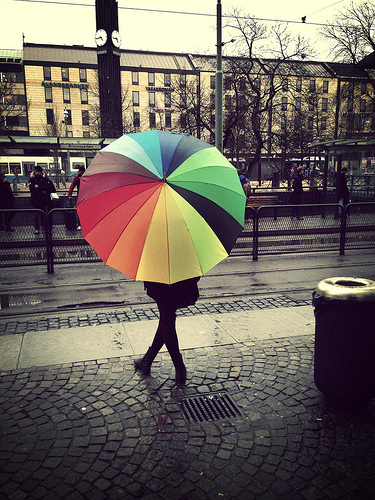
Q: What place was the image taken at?
A: It was taken at the sidewalk.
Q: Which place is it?
A: It is a sidewalk.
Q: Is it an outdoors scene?
A: Yes, it is outdoors.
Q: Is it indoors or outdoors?
A: It is outdoors.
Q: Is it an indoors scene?
A: No, it is outdoors.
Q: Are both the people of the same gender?
A: No, they are both male and female.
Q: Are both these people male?
A: No, they are both male and female.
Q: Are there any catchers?
A: No, there are no catchers.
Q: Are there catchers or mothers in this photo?
A: No, there are no catchers or mothers.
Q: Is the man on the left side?
A: Yes, the man is on the left of the image.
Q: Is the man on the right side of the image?
A: No, the man is on the left of the image.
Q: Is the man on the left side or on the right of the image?
A: The man is on the left of the image.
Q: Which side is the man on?
A: The man is on the left of the image.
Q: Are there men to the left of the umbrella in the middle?
A: Yes, there is a man to the left of the umbrella.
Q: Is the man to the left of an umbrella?
A: Yes, the man is to the left of an umbrella.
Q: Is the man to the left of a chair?
A: No, the man is to the left of an umbrella.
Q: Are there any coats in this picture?
A: Yes, there is a coat.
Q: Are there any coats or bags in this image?
A: Yes, there is a coat.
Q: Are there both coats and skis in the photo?
A: No, there is a coat but no skis.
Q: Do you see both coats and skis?
A: No, there is a coat but no skis.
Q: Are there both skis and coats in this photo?
A: No, there is a coat but no skis.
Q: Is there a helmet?
A: No, there are no helmets.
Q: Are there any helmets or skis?
A: No, there are no helmets or skis.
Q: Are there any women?
A: Yes, there is a woman.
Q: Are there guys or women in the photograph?
A: Yes, there is a woman.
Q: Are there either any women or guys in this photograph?
A: Yes, there is a woman.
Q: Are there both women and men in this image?
A: Yes, there are both a woman and a man.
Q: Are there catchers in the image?
A: No, there are no catchers.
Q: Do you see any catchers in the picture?
A: No, there are no catchers.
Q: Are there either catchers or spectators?
A: No, there are no catchers or spectators.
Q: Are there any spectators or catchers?
A: No, there are no catchers or spectators.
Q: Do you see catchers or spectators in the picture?
A: No, there are no catchers or spectators.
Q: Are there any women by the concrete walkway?
A: Yes, there is a woman by the walkway.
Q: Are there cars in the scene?
A: No, there are no cars.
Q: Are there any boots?
A: Yes, there are boots.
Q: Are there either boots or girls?
A: Yes, there are boots.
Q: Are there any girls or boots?
A: Yes, there are boots.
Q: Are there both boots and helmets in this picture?
A: No, there are boots but no helmets.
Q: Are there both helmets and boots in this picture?
A: No, there are boots but no helmets.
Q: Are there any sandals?
A: No, there are no sandals.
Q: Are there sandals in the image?
A: No, there are no sandals.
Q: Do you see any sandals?
A: No, there are no sandals.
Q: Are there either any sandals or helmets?
A: No, there are no sandals or helmets.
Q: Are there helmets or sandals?
A: No, there are no sandals or helmets.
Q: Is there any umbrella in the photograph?
A: Yes, there is an umbrella.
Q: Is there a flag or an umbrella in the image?
A: Yes, there is an umbrella.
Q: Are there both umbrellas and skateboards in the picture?
A: No, there is an umbrella but no skateboards.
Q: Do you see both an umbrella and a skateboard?
A: No, there is an umbrella but no skateboards.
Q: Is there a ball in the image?
A: No, there are no balls.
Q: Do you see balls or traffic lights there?
A: No, there are no balls or traffic lights.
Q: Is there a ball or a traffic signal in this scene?
A: No, there are no balls or traffic lights.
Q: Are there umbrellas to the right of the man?
A: Yes, there is an umbrella to the right of the man.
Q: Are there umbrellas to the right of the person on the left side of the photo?
A: Yes, there is an umbrella to the right of the man.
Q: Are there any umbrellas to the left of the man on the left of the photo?
A: No, the umbrella is to the right of the man.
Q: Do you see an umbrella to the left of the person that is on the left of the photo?
A: No, the umbrella is to the right of the man.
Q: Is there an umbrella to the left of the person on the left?
A: No, the umbrella is to the right of the man.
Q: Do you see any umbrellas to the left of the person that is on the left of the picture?
A: No, the umbrella is to the right of the man.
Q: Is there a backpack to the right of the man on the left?
A: No, there is an umbrella to the right of the man.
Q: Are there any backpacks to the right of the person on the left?
A: No, there is an umbrella to the right of the man.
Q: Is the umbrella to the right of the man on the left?
A: Yes, the umbrella is to the right of the man.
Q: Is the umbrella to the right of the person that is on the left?
A: Yes, the umbrella is to the right of the man.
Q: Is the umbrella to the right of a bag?
A: No, the umbrella is to the right of the man.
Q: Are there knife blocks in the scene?
A: No, there are no knife blocks.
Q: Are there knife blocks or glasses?
A: No, there are no knife blocks or glasses.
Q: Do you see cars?
A: No, there are no cars.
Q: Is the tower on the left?
A: Yes, the tower is on the left of the image.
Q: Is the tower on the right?
A: No, the tower is on the left of the image.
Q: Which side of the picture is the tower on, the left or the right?
A: The tower is on the left of the image.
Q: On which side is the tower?
A: The tower is on the left of the image.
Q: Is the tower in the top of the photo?
A: Yes, the tower is in the top of the image.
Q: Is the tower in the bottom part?
A: No, the tower is in the top of the image.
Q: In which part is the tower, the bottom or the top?
A: The tower is in the top of the image.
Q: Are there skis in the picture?
A: No, there are no skis.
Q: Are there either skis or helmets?
A: No, there are no skis or helmets.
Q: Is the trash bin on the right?
A: Yes, the trash bin is on the right of the image.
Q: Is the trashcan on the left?
A: No, the trashcan is on the right of the image.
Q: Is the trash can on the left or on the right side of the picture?
A: The trash can is on the right of the image.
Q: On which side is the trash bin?
A: The trash bin is on the right of the image.